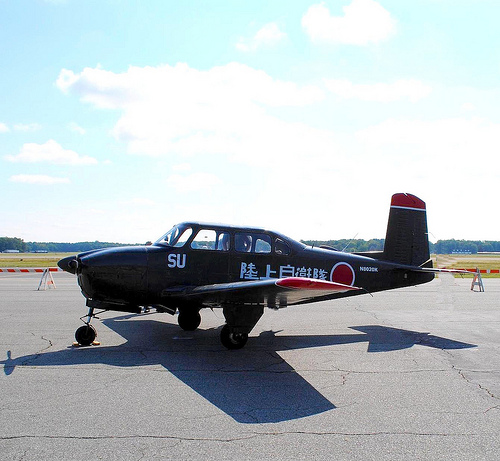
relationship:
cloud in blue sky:
[297, 0, 400, 50] [0, 0, 500, 231]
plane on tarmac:
[57, 192, 480, 344] [0, 268, 480, 460]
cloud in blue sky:
[297, 0, 400, 50] [0, 0, 500, 216]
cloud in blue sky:
[57, 62, 322, 169] [0, 0, 500, 231]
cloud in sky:
[297, 0, 400, 50] [5, 9, 473, 193]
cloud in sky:
[297, 0, 400, 50] [0, 2, 498, 197]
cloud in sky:
[297, 0, 400, 50] [305, 32, 457, 128]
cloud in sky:
[297, 0, 400, 50] [2, 1, 499, 281]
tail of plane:
[384, 192, 429, 264] [57, 192, 480, 344]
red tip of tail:
[385, 186, 432, 216] [384, 190, 433, 266]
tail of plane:
[384, 190, 433, 266] [57, 192, 480, 344]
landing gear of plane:
[74, 322, 101, 348] [57, 192, 480, 344]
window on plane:
[189, 227, 229, 250] [57, 192, 480, 344]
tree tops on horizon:
[0, 237, 499, 254] [0, 204, 498, 256]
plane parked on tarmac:
[57, 192, 483, 352] [275, 309, 478, 452]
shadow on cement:
[5, 315, 479, 421] [68, 427, 254, 459]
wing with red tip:
[175, 274, 360, 299] [387, 194, 433, 210]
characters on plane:
[238, 260, 332, 285] [57, 192, 480, 344]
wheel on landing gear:
[216, 320, 249, 353] [71, 305, 270, 360]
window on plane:
[189, 227, 231, 256] [53, 187, 492, 359]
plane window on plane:
[231, 227, 276, 259] [53, 187, 492, 359]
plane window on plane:
[150, 222, 195, 249] [53, 187, 492, 359]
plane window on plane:
[152, 221, 196, 248] [23, 124, 474, 410]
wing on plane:
[183, 274, 360, 299] [57, 192, 483, 352]